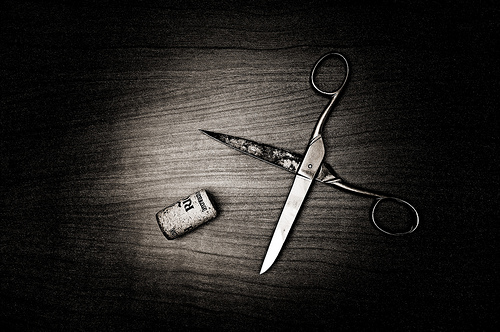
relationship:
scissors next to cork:
[196, 43, 453, 283] [143, 170, 237, 240]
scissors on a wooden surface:
[183, 40, 429, 280] [6, 7, 493, 328]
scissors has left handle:
[183, 40, 429, 280] [352, 185, 435, 241]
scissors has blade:
[183, 40, 429, 280] [256, 174, 311, 276]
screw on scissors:
[307, 162, 314, 168] [183, 40, 429, 280]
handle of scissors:
[299, 47, 351, 130] [183, 40, 429, 280]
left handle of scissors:
[352, 185, 435, 241] [183, 40, 429, 280]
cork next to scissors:
[152, 187, 219, 248] [183, 40, 429, 280]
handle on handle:
[299, 47, 351, 130] [307, 48, 337, 176]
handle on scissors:
[307, 48, 337, 176] [193, 24, 453, 278]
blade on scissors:
[196, 121, 291, 175] [183, 40, 429, 280]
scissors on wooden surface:
[183, 40, 429, 280] [6, 7, 493, 328]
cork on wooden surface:
[152, 187, 219, 248] [6, 7, 493, 328]